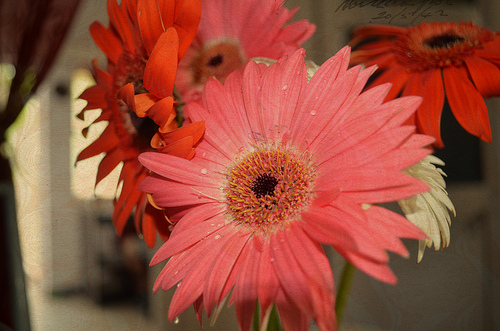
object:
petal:
[282, 221, 341, 298]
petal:
[319, 123, 414, 175]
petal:
[391, 193, 429, 264]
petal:
[419, 190, 451, 252]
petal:
[425, 181, 462, 217]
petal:
[148, 180, 222, 210]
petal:
[422, 153, 449, 167]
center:
[218, 144, 318, 229]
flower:
[170, 0, 317, 106]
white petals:
[305, 59, 320, 84]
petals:
[89, 56, 113, 88]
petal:
[420, 66, 444, 149]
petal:
[435, 57, 499, 144]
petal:
[118, 82, 153, 117]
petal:
[350, 40, 400, 68]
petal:
[236, 233, 260, 331]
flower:
[135, 44, 437, 331]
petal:
[86, 147, 125, 194]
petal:
[82, 107, 115, 136]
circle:
[249, 170, 279, 195]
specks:
[360, 203, 372, 210]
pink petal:
[166, 202, 199, 222]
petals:
[163, 116, 203, 156]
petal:
[202, 225, 253, 323]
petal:
[309, 281, 340, 330]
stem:
[330, 262, 348, 330]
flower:
[71, 0, 211, 249]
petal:
[295, 62, 363, 150]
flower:
[236, 54, 460, 264]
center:
[384, 19, 493, 71]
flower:
[347, 17, 498, 149]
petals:
[135, 172, 200, 194]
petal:
[367, 63, 406, 103]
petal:
[306, 187, 337, 208]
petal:
[277, 49, 302, 144]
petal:
[241, 59, 267, 150]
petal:
[147, 30, 177, 99]